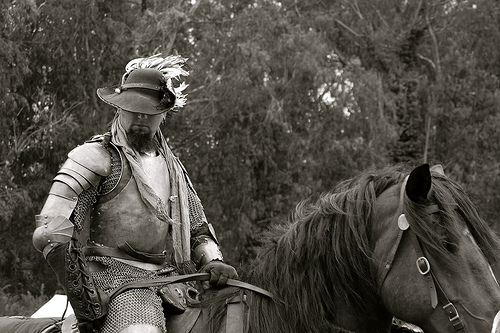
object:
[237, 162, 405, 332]
mane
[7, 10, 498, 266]
tree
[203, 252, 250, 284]
hand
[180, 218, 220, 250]
metal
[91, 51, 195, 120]
hat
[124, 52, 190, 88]
feathers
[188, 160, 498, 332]
mane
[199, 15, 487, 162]
forest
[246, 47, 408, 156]
forest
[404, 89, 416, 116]
forest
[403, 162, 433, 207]
ear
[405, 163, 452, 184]
ear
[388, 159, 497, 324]
head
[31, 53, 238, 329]
man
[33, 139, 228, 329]
armor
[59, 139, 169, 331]
chain maille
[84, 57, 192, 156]
head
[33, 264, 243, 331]
saddle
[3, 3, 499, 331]
photograph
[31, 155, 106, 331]
arm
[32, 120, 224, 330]
costume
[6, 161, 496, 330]
horse